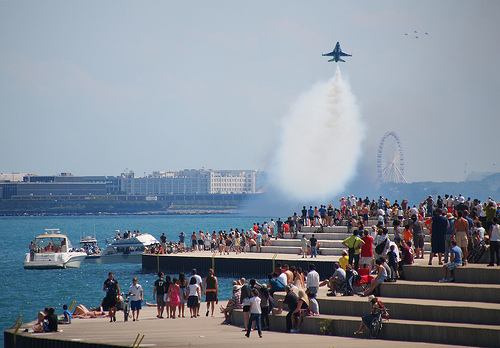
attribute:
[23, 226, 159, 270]
boats — for fishing, in the river thames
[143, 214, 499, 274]
stairs — cement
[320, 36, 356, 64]
jet — trailing smoke, leaving a trail, shooting into air, flying upwards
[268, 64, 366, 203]
trail — from  jet, white cloud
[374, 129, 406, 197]
ferris wheel — afar, in background, in the distance, in the background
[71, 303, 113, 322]
woman — sunbathing, in a bikini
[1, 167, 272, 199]
hotels — in the background, along the water, in the distance, large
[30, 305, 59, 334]
people — sitting, by the water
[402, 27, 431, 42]
jets — above the crowd, in the far distance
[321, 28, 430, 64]
air show — on the thames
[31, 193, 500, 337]
spectators — watching the jets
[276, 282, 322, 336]
people — sitting on the steps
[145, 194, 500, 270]
people — watching tricks, watching an airshow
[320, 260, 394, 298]
people — sitting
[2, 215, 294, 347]
water — blue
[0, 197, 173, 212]
hillside — green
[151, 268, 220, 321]
people — walking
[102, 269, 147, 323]
people — walking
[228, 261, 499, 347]
steps — cement